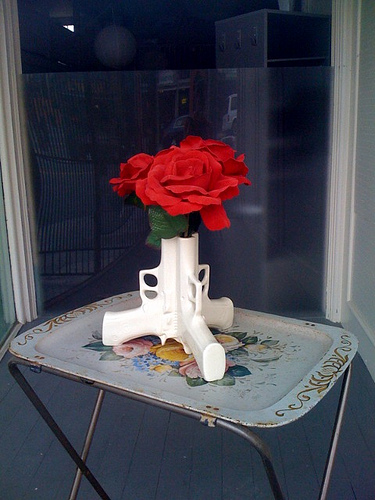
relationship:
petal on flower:
[200, 202, 234, 232] [114, 133, 252, 236]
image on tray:
[83, 326, 283, 392] [9, 290, 361, 432]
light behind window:
[92, 24, 137, 69] [18, 2, 332, 318]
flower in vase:
[114, 133, 252, 236] [100, 232, 239, 383]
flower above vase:
[114, 133, 252, 236] [100, 232, 239, 383]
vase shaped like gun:
[100, 232, 239, 383] [175, 237, 227, 385]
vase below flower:
[100, 232, 239, 383] [114, 133, 252, 236]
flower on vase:
[114, 133, 252, 236] [100, 232, 239, 383]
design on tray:
[272, 331, 358, 419] [9, 290, 361, 432]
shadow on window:
[264, 67, 327, 260] [18, 2, 332, 318]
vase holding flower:
[100, 232, 239, 383] [114, 133, 252, 236]